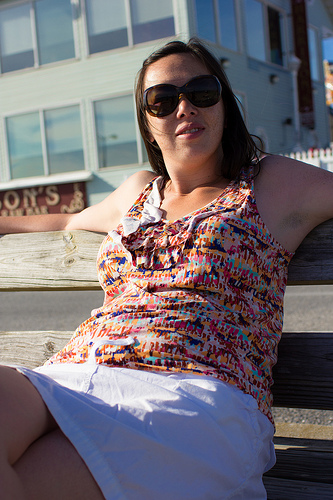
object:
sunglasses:
[141, 72, 229, 118]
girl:
[1, 34, 332, 498]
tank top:
[41, 145, 299, 427]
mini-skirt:
[13, 354, 277, 500]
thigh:
[0, 387, 105, 499]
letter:
[3, 185, 61, 213]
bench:
[1, 218, 332, 500]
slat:
[266, 437, 333, 466]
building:
[0, 0, 332, 206]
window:
[1, 100, 88, 187]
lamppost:
[284, 52, 306, 150]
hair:
[231, 120, 241, 138]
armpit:
[282, 209, 311, 229]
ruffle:
[109, 172, 250, 270]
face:
[142, 48, 227, 166]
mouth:
[175, 121, 207, 140]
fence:
[276, 147, 332, 171]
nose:
[176, 91, 199, 119]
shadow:
[0, 334, 332, 500]